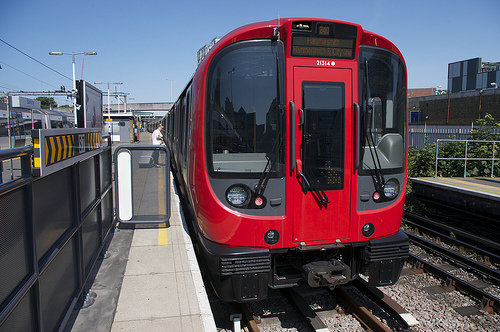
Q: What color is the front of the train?
A: Red.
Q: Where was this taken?
A: Train station.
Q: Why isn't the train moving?
A: Loading passengers.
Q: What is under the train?
A: Tracks.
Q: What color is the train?
A: Red.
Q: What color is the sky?
A: Blue.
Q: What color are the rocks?
A: Gray.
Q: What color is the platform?
A: Brown.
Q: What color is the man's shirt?
A: White.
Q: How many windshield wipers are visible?
A: 3.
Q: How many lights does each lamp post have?
A: 2.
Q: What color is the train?
A: Red.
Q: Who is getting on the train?
A: The man.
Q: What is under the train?
A: Train tracks.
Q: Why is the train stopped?
A: Picking up passengers.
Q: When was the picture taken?
A: Daytime.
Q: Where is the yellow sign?
A: Beside the train.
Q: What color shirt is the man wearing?
A: White.